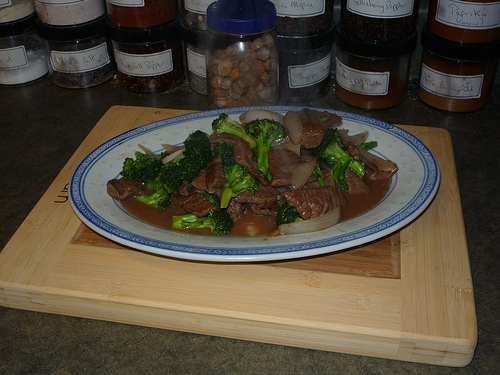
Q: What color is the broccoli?
A: Green.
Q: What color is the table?
A: Gray.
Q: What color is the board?
A: Brown.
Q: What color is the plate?
A: White.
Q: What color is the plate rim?
A: Blue.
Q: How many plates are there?
A: One.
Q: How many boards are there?
A: One.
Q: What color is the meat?
A: Brown.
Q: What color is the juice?
A: Brown.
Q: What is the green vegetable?
A: Broccoli.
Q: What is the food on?
A: A plate.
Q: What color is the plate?
A: Blue and white.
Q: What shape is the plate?
A: Round.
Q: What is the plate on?
A: A board.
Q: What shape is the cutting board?
A: Square.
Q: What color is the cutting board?
A: Light brown and dark brown.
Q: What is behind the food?
A: Jars.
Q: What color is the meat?
A: Brown.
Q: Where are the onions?
A: On the plate.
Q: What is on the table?
A: A square cutting board.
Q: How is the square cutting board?
A: It is two toned.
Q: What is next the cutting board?
A: A jar with blue lid.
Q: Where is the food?
A: On a blue and white dinner plate?.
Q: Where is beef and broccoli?
A: On a plate.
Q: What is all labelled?
A: Jars of spices.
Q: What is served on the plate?
A: Beef and broccoli.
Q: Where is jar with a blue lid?
A: Next to the wooden board.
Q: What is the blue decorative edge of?
A: A white plate.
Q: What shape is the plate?
A: Circle.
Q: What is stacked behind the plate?
A: Jars.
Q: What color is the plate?
A: White and blue.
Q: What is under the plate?
A: A board.